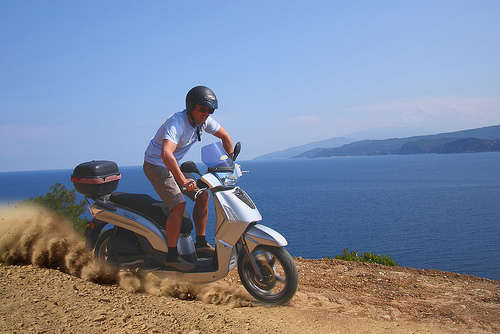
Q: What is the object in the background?
A: A grill.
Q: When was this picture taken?
A: Daytime.